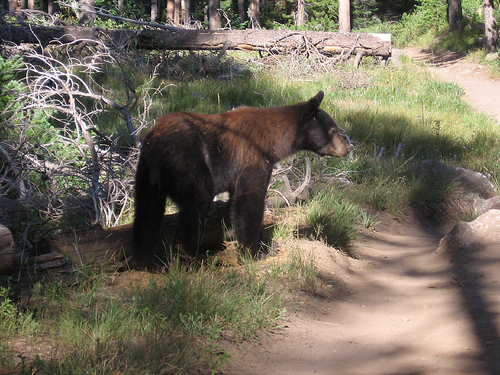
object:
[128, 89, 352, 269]
bear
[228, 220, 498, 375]
road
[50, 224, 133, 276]
log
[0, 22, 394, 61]
tree trunk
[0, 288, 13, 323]
grass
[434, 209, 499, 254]
stone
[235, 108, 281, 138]
fur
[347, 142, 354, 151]
snout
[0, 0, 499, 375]
field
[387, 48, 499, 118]
dirt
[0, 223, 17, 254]
woods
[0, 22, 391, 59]
tree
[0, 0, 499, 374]
ground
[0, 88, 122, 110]
branches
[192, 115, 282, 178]
shadow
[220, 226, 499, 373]
dirt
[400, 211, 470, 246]
groove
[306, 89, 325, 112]
ear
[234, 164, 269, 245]
leg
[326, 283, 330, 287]
stones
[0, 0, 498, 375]
nature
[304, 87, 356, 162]
head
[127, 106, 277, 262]
body